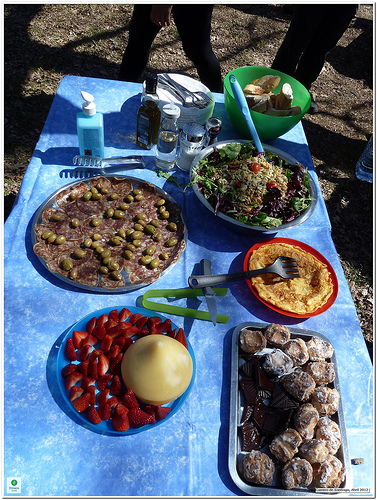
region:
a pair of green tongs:
[140, 289, 234, 321]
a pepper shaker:
[205, 117, 222, 146]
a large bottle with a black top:
[134, 70, 163, 152]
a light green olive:
[91, 214, 103, 224]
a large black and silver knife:
[200, 256, 220, 328]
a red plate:
[243, 239, 340, 321]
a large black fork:
[186, 254, 299, 287]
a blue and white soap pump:
[75, 91, 107, 164]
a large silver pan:
[226, 320, 346, 498]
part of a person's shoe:
[304, 100, 321, 116]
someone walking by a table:
[115, 12, 244, 91]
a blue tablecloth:
[57, 448, 144, 486]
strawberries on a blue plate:
[49, 309, 198, 433]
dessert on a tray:
[224, 320, 362, 492]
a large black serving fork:
[185, 254, 301, 288]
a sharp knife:
[195, 257, 224, 328]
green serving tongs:
[141, 282, 236, 326]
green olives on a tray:
[23, 170, 194, 299]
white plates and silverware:
[140, 67, 216, 125]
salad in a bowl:
[188, 132, 326, 237]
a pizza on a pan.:
[15, 158, 191, 305]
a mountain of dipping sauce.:
[119, 327, 215, 418]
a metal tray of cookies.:
[220, 313, 360, 495]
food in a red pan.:
[227, 235, 352, 342]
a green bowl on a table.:
[205, 62, 332, 140]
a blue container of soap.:
[59, 71, 123, 174]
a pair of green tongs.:
[131, 246, 253, 351]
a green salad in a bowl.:
[164, 115, 330, 245]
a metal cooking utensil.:
[180, 240, 318, 305]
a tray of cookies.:
[235, 323, 353, 497]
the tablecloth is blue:
[1, 57, 370, 496]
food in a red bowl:
[236, 238, 358, 330]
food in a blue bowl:
[34, 290, 209, 436]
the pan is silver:
[223, 310, 353, 496]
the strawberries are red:
[52, 299, 220, 432]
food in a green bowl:
[208, 62, 312, 138]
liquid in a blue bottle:
[53, 104, 114, 170]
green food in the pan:
[43, 173, 205, 290]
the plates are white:
[152, 68, 218, 141]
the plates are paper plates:
[136, 68, 218, 133]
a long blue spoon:
[226, 74, 265, 150]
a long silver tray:
[225, 319, 352, 498]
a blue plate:
[46, 304, 197, 437]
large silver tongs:
[159, 72, 210, 107]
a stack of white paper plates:
[145, 73, 213, 124]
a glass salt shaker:
[176, 119, 205, 172]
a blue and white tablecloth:
[3, 69, 376, 495]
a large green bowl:
[221, 64, 310, 137]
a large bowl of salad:
[193, 137, 316, 232]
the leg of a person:
[171, 0, 227, 95]